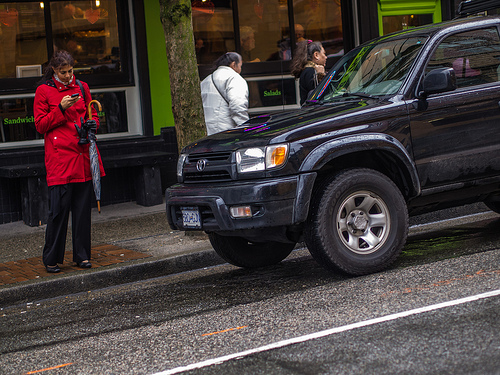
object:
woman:
[290, 39, 328, 106]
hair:
[290, 36, 323, 76]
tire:
[302, 167, 410, 277]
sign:
[264, 89, 282, 96]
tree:
[159, 0, 206, 158]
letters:
[4, 116, 35, 125]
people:
[33, 50, 107, 273]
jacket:
[34, 74, 107, 187]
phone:
[71, 93, 80, 100]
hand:
[60, 94, 81, 110]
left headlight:
[235, 144, 289, 174]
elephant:
[88, 99, 102, 214]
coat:
[200, 65, 250, 136]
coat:
[293, 67, 322, 106]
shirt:
[34, 74, 106, 187]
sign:
[180, 206, 203, 229]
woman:
[200, 52, 250, 136]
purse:
[211, 73, 230, 104]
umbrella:
[87, 99, 103, 211]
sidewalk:
[0, 199, 212, 292]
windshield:
[305, 36, 429, 105]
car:
[165, 13, 500, 278]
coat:
[33, 74, 107, 186]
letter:
[182, 213, 200, 223]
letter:
[263, 89, 281, 96]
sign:
[4, 112, 106, 125]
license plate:
[180, 206, 203, 229]